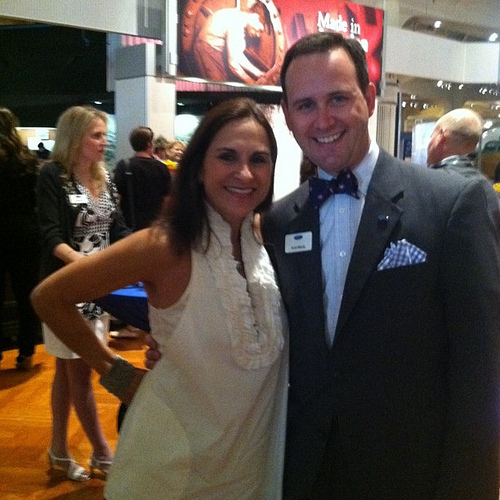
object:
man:
[267, 29, 496, 499]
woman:
[27, 83, 296, 497]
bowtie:
[305, 168, 364, 209]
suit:
[258, 168, 498, 500]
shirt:
[309, 139, 382, 353]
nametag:
[281, 232, 318, 258]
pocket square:
[371, 236, 434, 275]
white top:
[105, 203, 298, 500]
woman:
[19, 104, 131, 485]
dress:
[32, 158, 128, 360]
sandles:
[35, 445, 124, 485]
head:
[274, 28, 385, 173]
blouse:
[194, 204, 292, 375]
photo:
[3, 3, 499, 498]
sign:
[148, 3, 400, 97]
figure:
[193, 4, 275, 84]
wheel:
[175, 3, 291, 93]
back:
[423, 108, 488, 171]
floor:
[0, 375, 40, 500]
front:
[191, 221, 291, 470]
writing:
[285, 241, 312, 252]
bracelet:
[94, 353, 143, 398]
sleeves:
[28, 171, 77, 259]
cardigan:
[26, 159, 141, 293]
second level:
[389, 1, 499, 53]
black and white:
[27, 162, 125, 359]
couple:
[29, 30, 497, 497]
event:
[1, 8, 496, 499]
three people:
[122, 123, 187, 165]